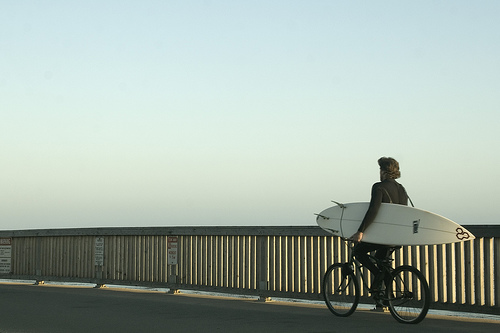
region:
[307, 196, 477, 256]
surfboard under the left arm of man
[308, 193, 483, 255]
surfboard is white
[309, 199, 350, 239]
surfboard has three fins in the tail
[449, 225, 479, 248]
nose of surfboard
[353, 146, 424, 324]
man wears black wet suit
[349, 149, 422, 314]
man sits in a bike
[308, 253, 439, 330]
bike is black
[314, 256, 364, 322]
front wheel of bike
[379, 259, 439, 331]
back wheel of bike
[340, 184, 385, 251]
left hand holding a surfboard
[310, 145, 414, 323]
A man on a bicycle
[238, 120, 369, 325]
A man on a bicycle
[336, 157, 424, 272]
this is a man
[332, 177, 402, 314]
the man is on a bike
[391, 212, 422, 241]
this is a surf board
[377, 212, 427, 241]
the surf board is wide in size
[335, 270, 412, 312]
the bike is black in color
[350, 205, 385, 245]
the hand is on the board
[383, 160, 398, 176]
the hair is coiled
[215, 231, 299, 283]
this is a fence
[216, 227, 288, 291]
the fence is wooden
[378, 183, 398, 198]
the costume is black in color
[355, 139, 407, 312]
man in black wetsuit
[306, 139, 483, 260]
man holding white surfboard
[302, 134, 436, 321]
man on a bicycle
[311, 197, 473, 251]
a white surfboard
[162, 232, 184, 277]
red and white sign on railing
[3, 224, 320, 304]
slatted railing on edge of street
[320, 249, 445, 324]
a black bicycle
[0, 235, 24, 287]
warning sign on slatted railing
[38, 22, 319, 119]
blue cloudless sky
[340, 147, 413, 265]
man with a shaggy hairdo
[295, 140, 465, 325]
The man is riding a bicycle.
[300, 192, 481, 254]
The man is carrying a surfboard.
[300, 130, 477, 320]
Riding a bike and carrying a surfboard.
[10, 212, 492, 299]
The fence is near the man.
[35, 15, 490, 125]
The sky is light blue.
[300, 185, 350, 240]
The surfboard has three fins on the bottom.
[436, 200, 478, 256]
The surfboard is pointy.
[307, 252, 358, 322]
The front wheel of the bicycle.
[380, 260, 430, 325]
The back wheel of a bicycle.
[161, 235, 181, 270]
A sign on the fence.